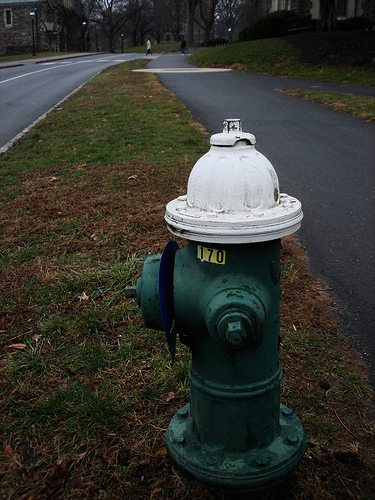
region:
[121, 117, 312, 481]
Green and white fire hydrant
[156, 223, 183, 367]
Blue disc on fire hydrant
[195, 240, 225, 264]
Black number on fire hydrant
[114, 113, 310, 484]
Fire hydrant on grass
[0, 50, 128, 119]
White traffic line on road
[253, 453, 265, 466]
Large bolt on fire hydrant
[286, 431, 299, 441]
Large bolt on fire hydrant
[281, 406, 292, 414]
Large bolt on fire hydrant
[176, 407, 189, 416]
Large bolt on fire hydrant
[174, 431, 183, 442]
Large bolt on fire hydrant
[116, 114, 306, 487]
White and green fire hydrant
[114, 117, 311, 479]
White and green fire hydrant on grass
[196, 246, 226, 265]
Yellow sticker on fire hydrant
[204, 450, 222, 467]
Green bolt on fire hydrant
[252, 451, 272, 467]
Green bolt on fire hydrant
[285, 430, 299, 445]
Green bolt on fire hydrant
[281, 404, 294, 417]
Green bolt on fire hydrant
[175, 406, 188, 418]
Green bolt on fire hydrant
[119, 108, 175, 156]
Grass in the photo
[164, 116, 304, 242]
A white cap in the photo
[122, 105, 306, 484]
A water hydrant in the photo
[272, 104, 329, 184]
Road with tarmac in the photo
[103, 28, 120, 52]
A tree trunk in the photo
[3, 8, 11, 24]
A window in the photo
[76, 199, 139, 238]
Dry grass in the photo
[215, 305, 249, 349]
A nut on the hydrant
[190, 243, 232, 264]
Numbers on the water hydrant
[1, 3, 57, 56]
A building in the photo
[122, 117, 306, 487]
a green and white fire hydrant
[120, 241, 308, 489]
the green base of a fire hydrant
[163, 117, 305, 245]
the white top of a fire hydrant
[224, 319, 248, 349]
the plug of a fire hydrant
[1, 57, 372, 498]
a median between two sides of a street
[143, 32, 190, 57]
two people crossing at an intersection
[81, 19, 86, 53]
a lamppost next to the street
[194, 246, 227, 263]
the number 170 displayed on a fire hydrant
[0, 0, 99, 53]
a country styled home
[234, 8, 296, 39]
bushes in front of a home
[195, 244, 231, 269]
number 170 on the hydrant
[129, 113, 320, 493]
green and white hydrant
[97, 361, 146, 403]
brown patches in the grass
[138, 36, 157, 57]
person walking on the road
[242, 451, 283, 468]
screw on the hydrant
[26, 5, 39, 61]
black street light on the side of the road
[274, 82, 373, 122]
grass in the middle of the road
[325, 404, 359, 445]
brown stick on the ground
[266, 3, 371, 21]
white house in the background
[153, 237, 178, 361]
blue tag on the hydrant